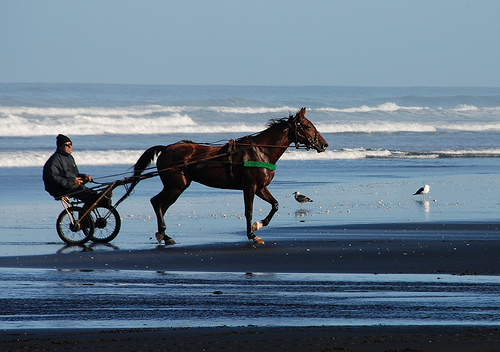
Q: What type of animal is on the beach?
A: A horse.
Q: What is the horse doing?
A: Trotting on the beach.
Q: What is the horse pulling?
A: A man in a two wheeled buggy.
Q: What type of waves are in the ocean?
A: White capped waves.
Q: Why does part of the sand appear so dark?
A: The sand is dry.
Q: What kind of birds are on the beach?
A: Seagulls.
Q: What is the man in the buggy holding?
A: Horse reins.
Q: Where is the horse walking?
A: On the beach.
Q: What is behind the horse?
A: A person in a carriage.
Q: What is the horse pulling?
A: A carriage.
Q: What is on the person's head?
A: A cap.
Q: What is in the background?
A: The ocean.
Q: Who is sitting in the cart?
A: The man.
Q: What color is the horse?
A: Brown.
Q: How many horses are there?
A: 1.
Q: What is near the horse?
A: Some birds.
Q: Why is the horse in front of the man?
A: The horse is drawing the cart.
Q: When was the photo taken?
A: Day time.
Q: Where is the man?
A: Behind the horse.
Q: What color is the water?
A: Blue.